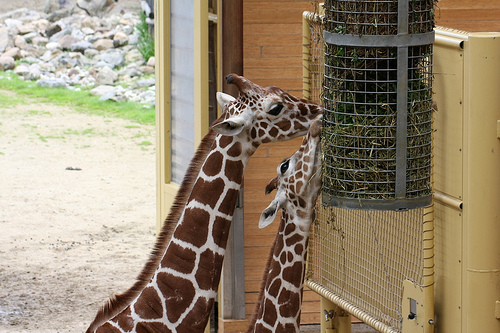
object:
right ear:
[264, 175, 278, 196]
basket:
[319, 0, 435, 210]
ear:
[257, 191, 288, 229]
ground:
[0, 90, 155, 333]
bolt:
[427, 319, 434, 325]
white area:
[241, 132, 247, 149]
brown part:
[201, 150, 224, 176]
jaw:
[314, 124, 323, 193]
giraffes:
[240, 120, 326, 333]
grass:
[325, 0, 432, 200]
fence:
[299, 10, 431, 333]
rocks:
[93, 64, 121, 87]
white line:
[139, 0, 151, 19]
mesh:
[405, 43, 430, 200]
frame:
[297, 11, 435, 333]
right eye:
[266, 102, 285, 116]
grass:
[0, 69, 160, 128]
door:
[153, 0, 221, 333]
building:
[152, 0, 497, 333]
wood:
[244, 0, 499, 325]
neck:
[243, 210, 316, 333]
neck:
[129, 129, 259, 307]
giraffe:
[82, 72, 329, 333]